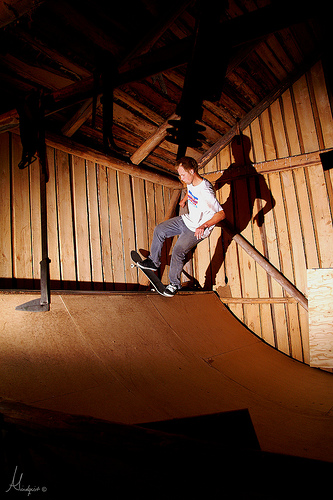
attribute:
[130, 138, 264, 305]
man — young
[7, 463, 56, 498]
name — corner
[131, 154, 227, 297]
man — young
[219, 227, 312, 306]
poles — some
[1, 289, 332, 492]
ramp — wooden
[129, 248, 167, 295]
skateboard — black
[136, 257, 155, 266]
sneaker — black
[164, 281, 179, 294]
sneaker — black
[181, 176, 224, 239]
white shirt — red, blue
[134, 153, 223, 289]
man — young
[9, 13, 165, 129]
beam — wooden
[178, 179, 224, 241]
shirt — white